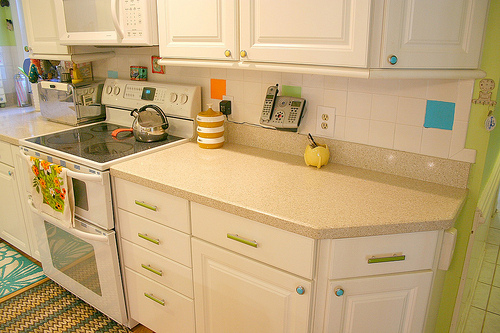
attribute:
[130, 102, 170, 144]
tea kettle — sitting on burner, black, silver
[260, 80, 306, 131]
telephone — silver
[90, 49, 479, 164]
tile — blue, white, tiled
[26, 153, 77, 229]
towel — hanging, green/yellow/orange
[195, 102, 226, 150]
container — striped, yellow/white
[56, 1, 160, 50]
microwave — white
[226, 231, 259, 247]
handle — green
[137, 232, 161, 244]
handle — green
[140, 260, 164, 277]
handle — green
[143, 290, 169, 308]
handle — green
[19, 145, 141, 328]
oven — double oven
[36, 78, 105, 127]
bread box — silver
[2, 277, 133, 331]
rug — striped, yellow/blue, in front of oven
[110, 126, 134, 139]
spoon rest — orange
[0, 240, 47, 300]
floor mat — blue/white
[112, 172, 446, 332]
cabinet — white